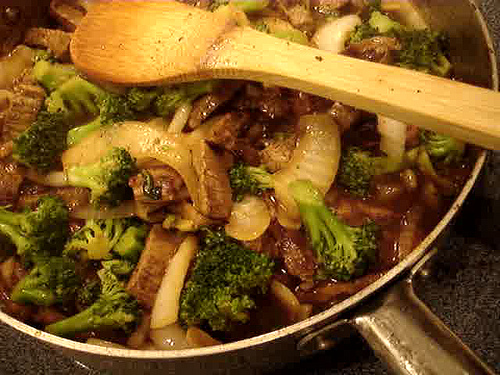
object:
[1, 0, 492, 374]
pot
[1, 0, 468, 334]
vegetables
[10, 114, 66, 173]
broccoli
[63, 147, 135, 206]
broccoli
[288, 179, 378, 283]
broccoli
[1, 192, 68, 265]
broccoli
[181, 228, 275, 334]
broccoli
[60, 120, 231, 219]
onion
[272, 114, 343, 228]
onion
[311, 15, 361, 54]
onion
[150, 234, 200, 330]
onion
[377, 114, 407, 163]
onion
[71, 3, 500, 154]
spoon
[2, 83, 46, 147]
meat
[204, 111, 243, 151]
meat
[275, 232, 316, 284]
meat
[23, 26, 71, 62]
meat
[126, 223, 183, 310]
meat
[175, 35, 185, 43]
speckles of food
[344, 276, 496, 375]
handle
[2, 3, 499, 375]
countertop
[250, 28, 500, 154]
handle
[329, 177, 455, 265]
gravy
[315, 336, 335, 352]
screw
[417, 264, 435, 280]
screw